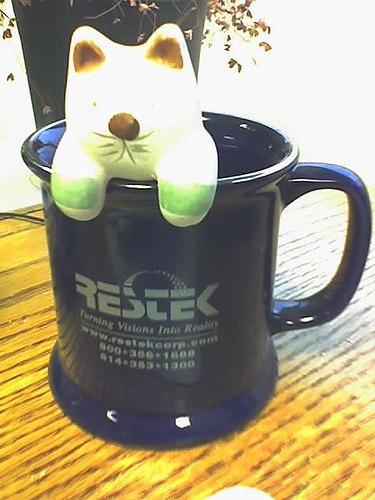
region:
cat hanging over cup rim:
[41, 15, 225, 232]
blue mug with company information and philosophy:
[21, 114, 366, 448]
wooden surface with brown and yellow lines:
[0, 210, 364, 495]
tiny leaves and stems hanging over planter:
[1, 0, 273, 120]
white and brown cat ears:
[60, 23, 195, 78]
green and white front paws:
[25, 165, 213, 228]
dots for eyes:
[85, 95, 154, 110]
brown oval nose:
[106, 109, 136, 139]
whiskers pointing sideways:
[92, 127, 148, 161]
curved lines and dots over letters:
[120, 263, 190, 295]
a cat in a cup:
[8, 14, 372, 468]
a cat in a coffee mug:
[13, 14, 374, 489]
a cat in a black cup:
[29, 18, 367, 488]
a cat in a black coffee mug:
[14, 16, 345, 461]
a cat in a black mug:
[32, 12, 335, 472]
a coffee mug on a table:
[22, 50, 373, 497]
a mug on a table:
[29, 70, 364, 495]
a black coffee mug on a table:
[17, 75, 370, 480]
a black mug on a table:
[4, 60, 362, 498]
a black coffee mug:
[9, 92, 328, 446]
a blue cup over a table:
[16, 103, 371, 459]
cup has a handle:
[24, 114, 373, 448]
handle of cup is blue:
[265, 150, 373, 339]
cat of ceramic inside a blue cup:
[15, 2, 370, 455]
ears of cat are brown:
[60, 20, 196, 74]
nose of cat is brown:
[105, 113, 143, 144]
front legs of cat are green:
[39, 159, 213, 227]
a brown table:
[6, 187, 373, 498]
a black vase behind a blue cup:
[4, 1, 295, 151]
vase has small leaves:
[0, 0, 278, 69]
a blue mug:
[18, 109, 370, 448]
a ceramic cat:
[49, 20, 214, 222]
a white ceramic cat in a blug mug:
[18, 22, 367, 445]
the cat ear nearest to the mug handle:
[145, 21, 190, 69]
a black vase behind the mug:
[7, 0, 206, 128]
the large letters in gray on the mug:
[70, 263, 217, 318]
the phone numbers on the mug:
[96, 339, 195, 369]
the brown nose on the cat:
[105, 110, 138, 140]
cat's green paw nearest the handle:
[157, 180, 211, 212]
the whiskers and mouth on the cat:
[93, 128, 153, 162]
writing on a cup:
[74, 269, 230, 374]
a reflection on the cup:
[166, 414, 200, 432]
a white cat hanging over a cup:
[55, 22, 218, 225]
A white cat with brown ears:
[48, 36, 219, 219]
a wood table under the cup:
[249, 300, 369, 459]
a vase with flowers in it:
[2, 0, 258, 36]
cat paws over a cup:
[44, 158, 224, 237]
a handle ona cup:
[264, 154, 373, 346]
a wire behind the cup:
[2, 197, 50, 240]